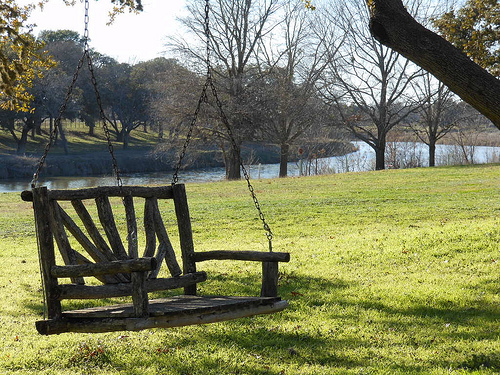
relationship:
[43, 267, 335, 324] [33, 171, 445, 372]
shadows on ground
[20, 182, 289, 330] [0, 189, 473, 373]
bench above grass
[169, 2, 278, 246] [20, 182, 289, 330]
chain holding up bench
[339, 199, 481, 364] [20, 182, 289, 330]
grass by bench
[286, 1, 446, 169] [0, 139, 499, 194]
tree by river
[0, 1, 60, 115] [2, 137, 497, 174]
trees across river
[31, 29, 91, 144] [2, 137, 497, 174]
trees across river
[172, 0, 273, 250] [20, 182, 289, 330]
chain holding on to bench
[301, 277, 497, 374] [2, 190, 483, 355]
shadows on ground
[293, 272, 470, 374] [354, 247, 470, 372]
shadow on ground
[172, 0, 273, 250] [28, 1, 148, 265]
chain on a chains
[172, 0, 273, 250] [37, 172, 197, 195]
chain on a wooden post